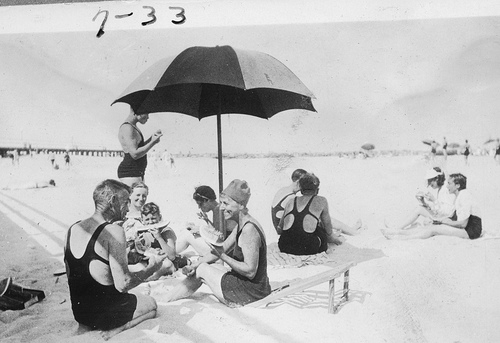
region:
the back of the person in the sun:
[278, 178, 346, 263]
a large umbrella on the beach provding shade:
[139, 40, 331, 128]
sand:
[416, 262, 459, 317]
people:
[40, 143, 270, 255]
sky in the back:
[333, 50, 496, 135]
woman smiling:
[209, 180, 249, 224]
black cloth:
[81, 297, 124, 317]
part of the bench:
[332, 267, 348, 309]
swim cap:
[234, 178, 256, 202]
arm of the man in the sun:
[141, 131, 176, 160]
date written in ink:
[88, 5, 197, 50]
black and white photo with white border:
[8, 12, 468, 323]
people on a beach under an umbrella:
[46, 37, 366, 322]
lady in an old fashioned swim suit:
[189, 179, 287, 308]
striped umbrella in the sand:
[104, 39, 326, 256]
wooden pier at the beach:
[7, 136, 119, 168]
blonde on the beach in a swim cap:
[211, 176, 258, 228]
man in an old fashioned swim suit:
[43, 168, 165, 331]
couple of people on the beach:
[379, 157, 486, 268]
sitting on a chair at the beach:
[270, 166, 365, 290]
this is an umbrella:
[148, 47, 286, 112]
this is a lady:
[218, 190, 269, 302]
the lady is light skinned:
[243, 234, 253, 257]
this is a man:
[69, 182, 129, 322]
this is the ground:
[389, 254, 486, 333]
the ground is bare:
[397, 252, 497, 317]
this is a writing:
[91, 3, 196, 35]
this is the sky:
[319, 5, 474, 93]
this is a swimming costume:
[71, 276, 96, 302]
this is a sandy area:
[4, 310, 76, 340]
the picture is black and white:
[15, 10, 487, 312]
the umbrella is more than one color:
[72, 43, 325, 147]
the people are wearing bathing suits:
[71, 173, 337, 274]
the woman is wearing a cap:
[195, 165, 271, 237]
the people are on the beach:
[14, 120, 411, 260]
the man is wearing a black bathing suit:
[22, 180, 152, 327]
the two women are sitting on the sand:
[368, 133, 486, 298]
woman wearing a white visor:
[417, 154, 447, 194]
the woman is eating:
[172, 178, 224, 230]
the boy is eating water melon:
[121, 198, 184, 251]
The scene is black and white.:
[0, 32, 499, 341]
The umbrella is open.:
[107, 41, 330, 146]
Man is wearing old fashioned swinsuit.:
[61, 175, 163, 338]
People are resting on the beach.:
[55, 165, 352, 340]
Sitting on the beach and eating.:
[55, 172, 271, 333]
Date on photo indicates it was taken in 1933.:
[87, 1, 190, 43]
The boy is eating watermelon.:
[130, 205, 181, 275]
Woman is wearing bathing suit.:
[153, 178, 270, 314]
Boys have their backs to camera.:
[265, 160, 355, 260]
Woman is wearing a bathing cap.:
[211, 177, 258, 225]